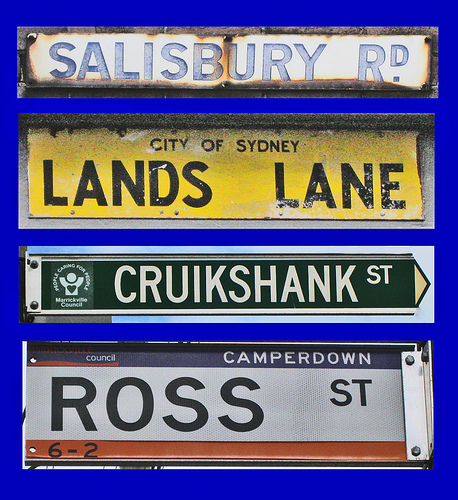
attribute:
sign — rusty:
[17, 25, 450, 148]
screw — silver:
[388, 343, 435, 386]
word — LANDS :
[38, 151, 211, 212]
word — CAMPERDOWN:
[222, 342, 384, 375]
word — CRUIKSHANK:
[106, 262, 376, 315]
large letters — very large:
[40, 355, 257, 440]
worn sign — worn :
[3, 15, 441, 109]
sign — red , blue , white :
[16, 339, 429, 473]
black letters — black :
[260, 158, 417, 219]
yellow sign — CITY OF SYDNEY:
[21, 123, 421, 220]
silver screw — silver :
[400, 352, 432, 371]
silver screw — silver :
[400, 354, 422, 365]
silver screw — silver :
[401, 353, 421, 374]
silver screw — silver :
[401, 353, 416, 368]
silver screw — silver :
[400, 347, 417, 366]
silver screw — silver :
[399, 349, 422, 373]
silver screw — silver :
[409, 350, 417, 373]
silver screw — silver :
[386, 344, 418, 370]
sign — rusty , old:
[11, 18, 444, 112]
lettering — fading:
[41, 147, 411, 216]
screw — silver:
[410, 445, 419, 455]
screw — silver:
[411, 445, 420, 454]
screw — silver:
[411, 445, 420, 455]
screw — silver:
[410, 444, 419, 454]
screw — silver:
[410, 445, 421, 454]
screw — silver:
[410, 446, 420, 455]